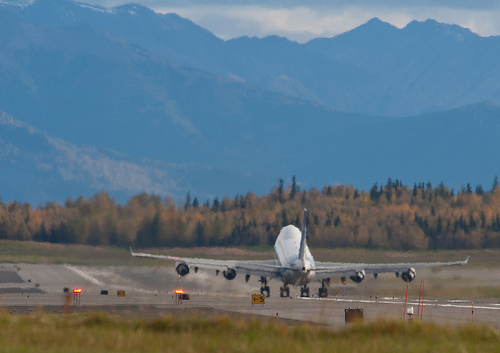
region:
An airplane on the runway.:
[60, 133, 477, 337]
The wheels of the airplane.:
[256, 278, 329, 295]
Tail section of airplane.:
[297, 195, 312, 269]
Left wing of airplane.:
[125, 241, 282, 273]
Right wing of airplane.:
[319, 254, 474, 273]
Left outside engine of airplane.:
[165, 256, 195, 281]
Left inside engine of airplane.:
[216, 263, 246, 285]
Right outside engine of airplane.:
[398, 258, 424, 288]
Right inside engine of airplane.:
[348, 266, 368, 284]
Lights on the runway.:
[48, 273, 225, 312]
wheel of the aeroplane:
[256, 281, 334, 306]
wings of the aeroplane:
[127, 241, 274, 289]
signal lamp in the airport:
[71, 284, 185, 314]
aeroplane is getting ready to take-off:
[123, 213, 483, 310]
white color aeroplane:
[273, 220, 330, 288]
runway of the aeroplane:
[32, 261, 499, 349]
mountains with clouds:
[98, 23, 453, 183]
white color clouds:
[246, 7, 479, 17]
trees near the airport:
[53, 193, 447, 238]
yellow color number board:
[248, 290, 269, 310]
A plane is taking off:
[7, 85, 492, 348]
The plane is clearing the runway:
[15, 95, 485, 322]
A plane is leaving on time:
[15, 82, 492, 318]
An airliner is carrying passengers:
[20, 121, 493, 332]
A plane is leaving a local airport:
[18, 102, 488, 350]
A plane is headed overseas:
[26, 60, 496, 336]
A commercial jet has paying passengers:
[43, 140, 494, 340]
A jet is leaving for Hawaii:
[15, 105, 490, 320]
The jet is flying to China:
[26, 105, 496, 331]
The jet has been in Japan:
[32, 57, 494, 327]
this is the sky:
[213, 40, 433, 152]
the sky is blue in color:
[345, 57, 468, 154]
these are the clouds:
[206, 2, 316, 27]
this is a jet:
[213, 218, 368, 310]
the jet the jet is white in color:
[280, 229, 292, 246]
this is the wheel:
[276, 286, 298, 303]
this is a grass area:
[175, 315, 266, 346]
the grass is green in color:
[226, 322, 268, 351]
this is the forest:
[338, 192, 485, 227]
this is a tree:
[287, 163, 302, 196]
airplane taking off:
[122, 206, 472, 300]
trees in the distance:
[3, 174, 496, 254]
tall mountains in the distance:
[0, 0, 497, 204]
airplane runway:
[2, 258, 496, 330]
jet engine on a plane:
[170, 260, 194, 277]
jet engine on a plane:
[218, 264, 238, 281]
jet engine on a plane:
[345, 266, 369, 285]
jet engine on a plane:
[396, 264, 421, 284]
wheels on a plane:
[255, 279, 333, 301]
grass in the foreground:
[2, 305, 497, 350]